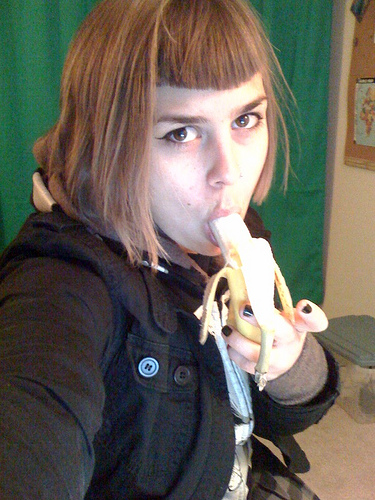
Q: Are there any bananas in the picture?
A: Yes, there is a banana.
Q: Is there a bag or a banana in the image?
A: Yes, there is a banana.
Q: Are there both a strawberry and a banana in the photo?
A: No, there is a banana but no strawberries.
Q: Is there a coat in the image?
A: Yes, there is a coat.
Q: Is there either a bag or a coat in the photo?
A: Yes, there is a coat.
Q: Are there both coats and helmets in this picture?
A: No, there is a coat but no helmets.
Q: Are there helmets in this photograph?
A: No, there are no helmets.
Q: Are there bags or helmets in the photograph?
A: No, there are no helmets or bags.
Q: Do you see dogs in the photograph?
A: No, there are no dogs.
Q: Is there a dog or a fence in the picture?
A: No, there are no dogs or fences.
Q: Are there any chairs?
A: No, there are no chairs.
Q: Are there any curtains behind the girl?
A: Yes, there is a curtain behind the girl.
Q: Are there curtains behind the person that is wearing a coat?
A: Yes, there is a curtain behind the girl.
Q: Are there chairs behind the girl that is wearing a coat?
A: No, there is a curtain behind the girl.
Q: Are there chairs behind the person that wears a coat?
A: No, there is a curtain behind the girl.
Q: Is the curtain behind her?
A: Yes, the curtain is behind the girl.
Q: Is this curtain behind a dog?
A: No, the curtain is behind the girl.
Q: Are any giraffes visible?
A: No, there are no giraffes.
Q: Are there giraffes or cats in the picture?
A: No, there are no giraffes or cats.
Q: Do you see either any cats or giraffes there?
A: No, there are no giraffes or cats.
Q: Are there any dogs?
A: No, there are no dogs.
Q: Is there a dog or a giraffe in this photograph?
A: No, there are no dogs or giraffes.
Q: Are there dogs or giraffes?
A: No, there are no dogs or giraffes.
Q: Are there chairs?
A: No, there are no chairs.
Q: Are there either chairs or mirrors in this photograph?
A: No, there are no chairs or mirrors.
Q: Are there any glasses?
A: No, there are no glasses.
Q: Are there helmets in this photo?
A: No, there are no helmets.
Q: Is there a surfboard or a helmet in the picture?
A: No, there are no helmets or surfboards.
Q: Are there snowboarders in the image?
A: No, there are no snowboarders.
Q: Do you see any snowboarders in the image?
A: No, there are no snowboarders.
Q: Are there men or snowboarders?
A: No, there are no snowboarders or men.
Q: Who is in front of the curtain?
A: The girl is in front of the curtain.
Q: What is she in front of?
A: The girl is in front of the curtain.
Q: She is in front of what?
A: The girl is in front of the curtain.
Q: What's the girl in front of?
A: The girl is in front of the curtain.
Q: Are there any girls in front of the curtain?
A: Yes, there is a girl in front of the curtain.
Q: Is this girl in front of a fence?
A: No, the girl is in front of the curtain.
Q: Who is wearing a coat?
A: The girl is wearing a coat.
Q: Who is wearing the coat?
A: The girl is wearing a coat.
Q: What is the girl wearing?
A: The girl is wearing a coat.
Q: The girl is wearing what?
A: The girl is wearing a coat.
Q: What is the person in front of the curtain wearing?
A: The girl is wearing a coat.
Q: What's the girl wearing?
A: The girl is wearing a coat.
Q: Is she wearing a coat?
A: Yes, the girl is wearing a coat.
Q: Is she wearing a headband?
A: No, the girl is wearing a coat.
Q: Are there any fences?
A: No, there are no fences.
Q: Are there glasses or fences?
A: No, there are no fences or glasses.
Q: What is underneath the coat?
A: The shirt is underneath the coat.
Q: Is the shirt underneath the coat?
A: Yes, the shirt is underneath the coat.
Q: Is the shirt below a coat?
A: Yes, the shirt is below a coat.